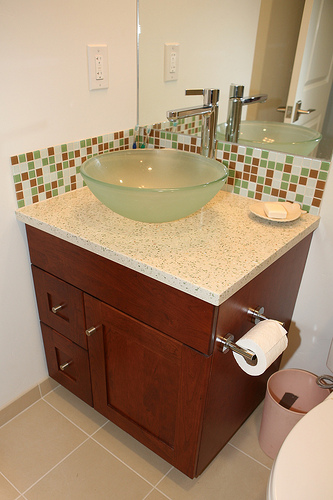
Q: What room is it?
A: It is a bathroom.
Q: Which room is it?
A: It is a bathroom.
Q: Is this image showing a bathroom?
A: Yes, it is showing a bathroom.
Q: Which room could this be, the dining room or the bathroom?
A: It is the bathroom.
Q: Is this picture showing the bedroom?
A: No, the picture is showing the bathroom.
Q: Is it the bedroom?
A: No, it is the bathroom.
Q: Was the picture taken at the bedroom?
A: No, the picture was taken in the bathroom.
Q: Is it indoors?
A: Yes, it is indoors.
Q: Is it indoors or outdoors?
A: It is indoors.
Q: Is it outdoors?
A: No, it is indoors.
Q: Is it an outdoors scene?
A: No, it is indoors.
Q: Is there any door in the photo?
A: Yes, there is a door.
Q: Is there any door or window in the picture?
A: Yes, there is a door.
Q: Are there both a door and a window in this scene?
A: No, there is a door but no windows.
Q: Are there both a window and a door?
A: No, there is a door but no windows.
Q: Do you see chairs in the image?
A: No, there are no chairs.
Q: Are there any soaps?
A: Yes, there is a soap.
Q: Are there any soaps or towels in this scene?
A: Yes, there is a soap.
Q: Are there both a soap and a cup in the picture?
A: No, there is a soap but no cups.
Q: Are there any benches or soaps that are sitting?
A: Yes, the soap is sitting.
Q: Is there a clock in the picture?
A: No, there are no clocks.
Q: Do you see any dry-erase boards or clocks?
A: No, there are no clocks or dry-erase boards.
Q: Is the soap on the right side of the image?
A: Yes, the soap is on the right of the image.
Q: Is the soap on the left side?
A: No, the soap is on the right of the image.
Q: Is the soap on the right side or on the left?
A: The soap is on the right of the image.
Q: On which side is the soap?
A: The soap is on the right of the image.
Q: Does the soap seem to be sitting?
A: Yes, the soap is sitting.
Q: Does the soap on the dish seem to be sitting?
A: Yes, the soap is sitting.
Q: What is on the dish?
A: The soap is on the dish.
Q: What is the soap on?
A: The soap is on the dish.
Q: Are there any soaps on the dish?
A: Yes, there is a soap on the dish.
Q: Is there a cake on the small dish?
A: No, there is a soap on the dish.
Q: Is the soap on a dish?
A: Yes, the soap is on a dish.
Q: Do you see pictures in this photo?
A: No, there are no pictures.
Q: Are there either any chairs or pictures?
A: No, there are no pictures or chairs.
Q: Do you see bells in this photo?
A: No, there are no bells.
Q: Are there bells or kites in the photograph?
A: No, there are no bells or kites.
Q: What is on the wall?
A: The electric outlet is on the wall.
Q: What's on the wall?
A: The electric outlet is on the wall.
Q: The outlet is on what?
A: The outlet is on the wall.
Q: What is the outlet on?
A: The outlet is on the wall.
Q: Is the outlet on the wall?
A: Yes, the outlet is on the wall.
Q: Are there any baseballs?
A: No, there are no baseballs.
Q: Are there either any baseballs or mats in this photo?
A: No, there are no baseballs or mats.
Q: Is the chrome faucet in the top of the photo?
A: Yes, the faucet is in the top of the image.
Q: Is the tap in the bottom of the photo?
A: No, the tap is in the top of the image.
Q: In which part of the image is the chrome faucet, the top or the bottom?
A: The faucet is in the top of the image.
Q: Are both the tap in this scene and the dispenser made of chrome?
A: Yes, both the tap and the dispenser are made of chrome.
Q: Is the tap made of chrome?
A: Yes, the tap is made of chrome.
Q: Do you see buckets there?
A: No, there are no buckets.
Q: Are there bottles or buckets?
A: No, there are no buckets or bottles.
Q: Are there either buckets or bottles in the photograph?
A: No, there are no buckets or bottles.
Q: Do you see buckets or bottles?
A: No, there are no buckets or bottles.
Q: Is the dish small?
A: Yes, the dish is small.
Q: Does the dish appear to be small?
A: Yes, the dish is small.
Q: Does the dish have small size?
A: Yes, the dish is small.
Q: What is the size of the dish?
A: The dish is small.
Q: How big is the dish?
A: The dish is small.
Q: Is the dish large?
A: No, the dish is small.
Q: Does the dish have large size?
A: No, the dish is small.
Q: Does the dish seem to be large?
A: No, the dish is small.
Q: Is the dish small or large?
A: The dish is small.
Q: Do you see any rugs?
A: No, there are no rugs.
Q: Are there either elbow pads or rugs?
A: No, there are no rugs or elbow pads.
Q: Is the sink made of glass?
A: Yes, the sink is made of glass.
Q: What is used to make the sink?
A: The sink is made of glass.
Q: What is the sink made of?
A: The sink is made of glass.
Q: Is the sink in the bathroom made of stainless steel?
A: No, the sink is made of glass.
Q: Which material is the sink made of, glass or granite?
A: The sink is made of glass.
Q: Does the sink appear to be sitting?
A: Yes, the sink is sitting.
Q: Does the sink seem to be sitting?
A: Yes, the sink is sitting.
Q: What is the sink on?
A: The sink is on the countertop.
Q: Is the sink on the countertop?
A: Yes, the sink is on the countertop.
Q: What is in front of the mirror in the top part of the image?
A: The sink is in front of the mirror.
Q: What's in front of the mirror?
A: The sink is in front of the mirror.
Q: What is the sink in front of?
A: The sink is in front of the mirror.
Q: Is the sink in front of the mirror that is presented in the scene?
A: Yes, the sink is in front of the mirror.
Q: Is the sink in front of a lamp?
A: No, the sink is in front of the mirror.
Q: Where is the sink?
A: The sink is in the bathroom.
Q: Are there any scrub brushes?
A: No, there are no scrub brushes.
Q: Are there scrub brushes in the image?
A: No, there are no scrub brushes.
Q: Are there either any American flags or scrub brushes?
A: No, there are no scrub brushes or American flags.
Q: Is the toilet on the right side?
A: Yes, the toilet is on the right of the image.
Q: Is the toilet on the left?
A: No, the toilet is on the right of the image.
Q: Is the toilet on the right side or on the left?
A: The toilet is on the right of the image.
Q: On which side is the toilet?
A: The toilet is on the right of the image.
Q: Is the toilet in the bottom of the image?
A: Yes, the toilet is in the bottom of the image.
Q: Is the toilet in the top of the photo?
A: No, the toilet is in the bottom of the image.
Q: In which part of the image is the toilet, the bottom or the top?
A: The toilet is in the bottom of the image.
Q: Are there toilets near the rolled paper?
A: Yes, there is a toilet near the paper.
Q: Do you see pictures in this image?
A: No, there are no pictures.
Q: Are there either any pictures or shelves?
A: No, there are no pictures or shelves.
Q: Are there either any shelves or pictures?
A: No, there are no pictures or shelves.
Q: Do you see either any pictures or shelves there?
A: No, there are no pictures or shelves.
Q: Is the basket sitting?
A: Yes, the basket is sitting.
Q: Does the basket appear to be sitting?
A: Yes, the basket is sitting.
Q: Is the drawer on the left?
A: Yes, the drawer is on the left of the image.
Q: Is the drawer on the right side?
A: No, the drawer is on the left of the image.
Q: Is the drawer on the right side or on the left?
A: The drawer is on the left of the image.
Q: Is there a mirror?
A: Yes, there is a mirror.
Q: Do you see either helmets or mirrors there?
A: Yes, there is a mirror.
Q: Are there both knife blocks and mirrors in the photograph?
A: No, there is a mirror but no knife blocks.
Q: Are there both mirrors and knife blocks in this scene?
A: No, there is a mirror but no knife blocks.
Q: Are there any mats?
A: No, there are no mats.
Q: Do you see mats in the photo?
A: No, there are no mats.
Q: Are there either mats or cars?
A: No, there are no mats or cars.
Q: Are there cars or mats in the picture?
A: No, there are no mats or cars.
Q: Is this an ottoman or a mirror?
A: This is a mirror.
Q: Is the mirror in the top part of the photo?
A: Yes, the mirror is in the top of the image.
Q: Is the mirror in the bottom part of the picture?
A: No, the mirror is in the top of the image.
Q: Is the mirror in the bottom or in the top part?
A: The mirror is in the top of the image.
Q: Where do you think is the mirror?
A: The mirror is in the bathroom.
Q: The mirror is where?
A: The mirror is in the bathroom.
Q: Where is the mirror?
A: The mirror is in the bathroom.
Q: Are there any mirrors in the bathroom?
A: Yes, there is a mirror in the bathroom.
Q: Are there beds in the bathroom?
A: No, there is a mirror in the bathroom.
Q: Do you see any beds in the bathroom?
A: No, there is a mirror in the bathroom.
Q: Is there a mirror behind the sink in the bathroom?
A: Yes, there is a mirror behind the sink.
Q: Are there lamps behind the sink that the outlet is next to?
A: No, there is a mirror behind the sink.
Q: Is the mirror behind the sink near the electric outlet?
A: Yes, the mirror is behind the sink.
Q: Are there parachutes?
A: No, there are no parachutes.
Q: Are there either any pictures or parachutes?
A: No, there are no parachutes or pictures.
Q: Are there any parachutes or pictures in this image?
A: No, there are no parachutes or pictures.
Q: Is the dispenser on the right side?
A: Yes, the dispenser is on the right of the image.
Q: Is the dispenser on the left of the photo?
A: No, the dispenser is on the right of the image.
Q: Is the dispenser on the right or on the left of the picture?
A: The dispenser is on the right of the image.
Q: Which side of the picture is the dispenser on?
A: The dispenser is on the right of the image.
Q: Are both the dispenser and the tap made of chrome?
A: Yes, both the dispenser and the tap are made of chrome.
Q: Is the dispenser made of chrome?
A: Yes, the dispenser is made of chrome.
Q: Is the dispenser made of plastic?
A: No, the dispenser is made of chrome.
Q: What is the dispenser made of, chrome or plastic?
A: The dispenser is made of chrome.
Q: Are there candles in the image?
A: No, there are no candles.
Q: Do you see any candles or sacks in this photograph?
A: No, there are no candles or sacks.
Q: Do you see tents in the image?
A: No, there are no tents.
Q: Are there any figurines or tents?
A: No, there are no tents or figurines.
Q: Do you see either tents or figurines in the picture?
A: No, there are no tents or figurines.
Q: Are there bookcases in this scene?
A: No, there are no bookcases.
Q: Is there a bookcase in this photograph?
A: No, there are no bookcases.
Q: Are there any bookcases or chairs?
A: No, there are no bookcases or chairs.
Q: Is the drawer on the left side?
A: Yes, the drawer is on the left of the image.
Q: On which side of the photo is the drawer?
A: The drawer is on the left of the image.